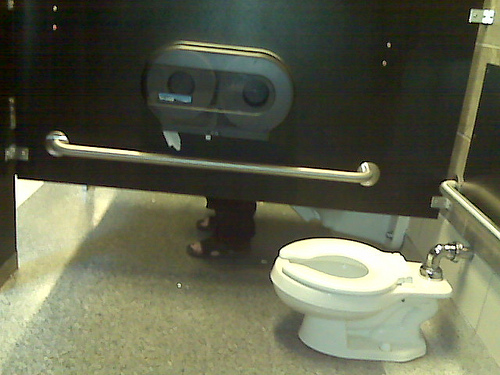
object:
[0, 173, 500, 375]
floor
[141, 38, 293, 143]
dispenser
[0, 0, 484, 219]
wall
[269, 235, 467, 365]
toilet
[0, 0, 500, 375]
restroom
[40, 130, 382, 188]
rail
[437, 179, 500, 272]
rail